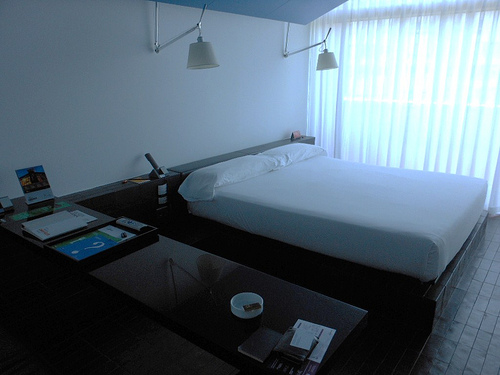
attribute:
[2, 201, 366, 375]
table — black, long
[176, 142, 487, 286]
bedspread — white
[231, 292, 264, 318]
bowl — white, small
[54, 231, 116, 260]
file — blue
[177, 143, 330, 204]
pillows — white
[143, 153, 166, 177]
remote — black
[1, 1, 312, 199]
wall — white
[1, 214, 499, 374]
floor — gray, black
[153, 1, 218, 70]
lamp — overhead, white, small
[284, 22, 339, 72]
lamp — overhead, white, small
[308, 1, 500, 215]
curtains — closed, white, sheer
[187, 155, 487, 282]
sheet — white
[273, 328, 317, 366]
wallet — black, thick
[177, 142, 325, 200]
pillow cases — white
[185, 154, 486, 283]
bed — neat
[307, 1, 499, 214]
window — bright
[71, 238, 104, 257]
question mark — white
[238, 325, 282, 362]
book — black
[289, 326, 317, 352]
business card — white